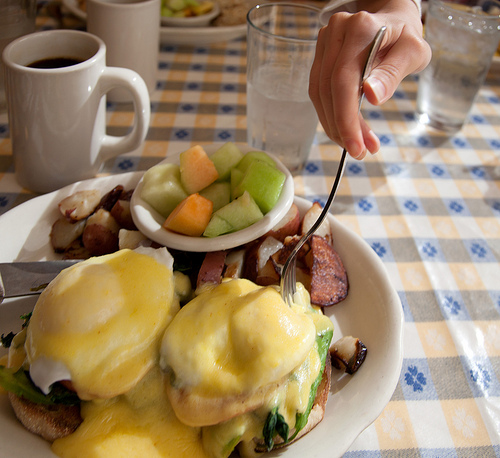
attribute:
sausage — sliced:
[304, 230, 352, 301]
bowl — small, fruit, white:
[125, 136, 298, 256]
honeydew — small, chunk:
[238, 154, 296, 214]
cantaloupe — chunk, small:
[177, 138, 220, 194]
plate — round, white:
[2, 165, 402, 454]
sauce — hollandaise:
[73, 343, 105, 364]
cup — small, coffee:
[6, 29, 150, 195]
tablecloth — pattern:
[412, 153, 489, 383]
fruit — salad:
[162, 141, 259, 238]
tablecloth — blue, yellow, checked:
[315, 151, 489, 455]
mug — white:
[1, 20, 130, 175]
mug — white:
[80, 0, 175, 100]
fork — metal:
[257, 37, 413, 315]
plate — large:
[36, 181, 369, 453]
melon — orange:
[179, 138, 225, 208]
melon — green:
[236, 156, 286, 206]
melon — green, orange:
[126, 132, 295, 245]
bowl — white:
[124, 132, 320, 276]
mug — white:
[13, 37, 122, 192]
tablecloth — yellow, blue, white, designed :
[0, 5, 496, 452]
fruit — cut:
[142, 142, 282, 235]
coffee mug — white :
[2, 28, 152, 189]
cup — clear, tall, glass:
[244, 2, 328, 176]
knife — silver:
[0, 260, 90, 301]